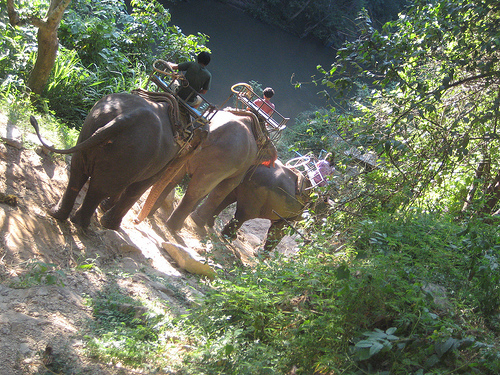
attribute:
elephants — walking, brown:
[31, 91, 329, 253]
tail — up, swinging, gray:
[28, 114, 137, 155]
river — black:
[120, 1, 387, 126]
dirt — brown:
[1, 108, 310, 373]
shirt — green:
[177, 61, 211, 102]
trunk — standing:
[6, 1, 72, 107]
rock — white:
[1, 126, 24, 150]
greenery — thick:
[0, 1, 498, 374]